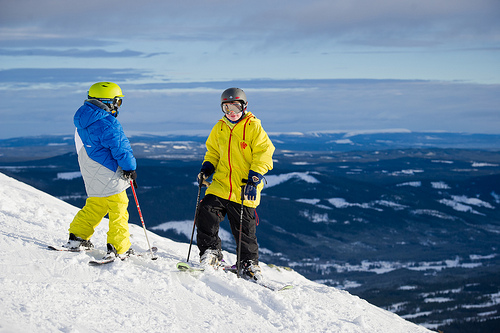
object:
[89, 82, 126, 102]
helmet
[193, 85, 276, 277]
person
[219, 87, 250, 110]
helmet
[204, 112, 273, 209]
jacket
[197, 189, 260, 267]
pants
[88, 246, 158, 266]
skis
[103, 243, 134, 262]
feet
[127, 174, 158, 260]
pole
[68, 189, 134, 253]
pants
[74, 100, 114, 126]
hood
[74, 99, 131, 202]
jacket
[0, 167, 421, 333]
snow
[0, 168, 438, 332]
ground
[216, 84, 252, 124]
head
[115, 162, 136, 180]
hand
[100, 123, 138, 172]
arm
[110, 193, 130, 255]
leg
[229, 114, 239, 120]
mouth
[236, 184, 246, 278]
pole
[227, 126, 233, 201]
zipper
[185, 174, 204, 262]
poles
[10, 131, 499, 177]
mountains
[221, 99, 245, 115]
goggles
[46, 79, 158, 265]
skiers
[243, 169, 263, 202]
gloves